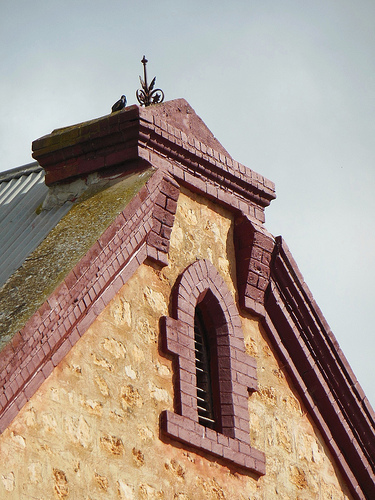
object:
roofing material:
[0, 173, 75, 288]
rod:
[144, 62, 147, 86]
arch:
[173, 259, 246, 352]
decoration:
[136, 55, 164, 106]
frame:
[159, 257, 266, 476]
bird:
[112, 95, 127, 113]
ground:
[326, 127, 347, 147]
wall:
[0, 186, 353, 500]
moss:
[0, 169, 155, 351]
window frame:
[158, 259, 266, 474]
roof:
[0, 99, 375, 418]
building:
[2, 98, 375, 499]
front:
[1, 98, 374, 500]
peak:
[140, 98, 234, 160]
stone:
[73, 354, 159, 498]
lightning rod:
[135, 55, 164, 106]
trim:
[154, 313, 205, 429]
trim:
[42, 257, 117, 352]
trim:
[281, 319, 347, 397]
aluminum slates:
[0, 168, 74, 286]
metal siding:
[0, 168, 73, 288]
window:
[193, 286, 235, 440]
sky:
[0, 0, 375, 407]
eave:
[263, 236, 375, 500]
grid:
[193, 309, 214, 427]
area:
[158, 258, 267, 476]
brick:
[0, 107, 375, 500]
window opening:
[194, 288, 235, 438]